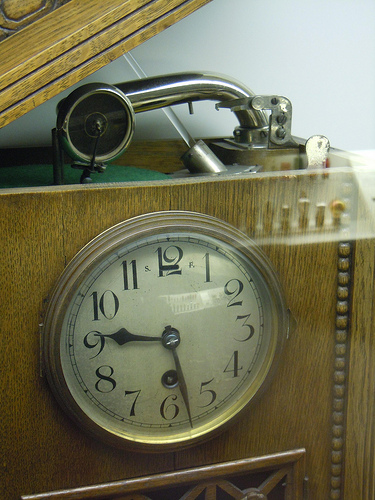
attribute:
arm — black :
[90, 328, 164, 350]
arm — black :
[170, 344, 196, 432]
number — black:
[85, 289, 121, 321]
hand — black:
[161, 325, 207, 424]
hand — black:
[95, 321, 182, 352]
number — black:
[114, 382, 155, 439]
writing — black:
[80, 290, 137, 330]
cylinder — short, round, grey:
[178, 132, 238, 181]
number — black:
[87, 360, 120, 395]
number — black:
[199, 377, 216, 408]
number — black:
[236, 314, 260, 344]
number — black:
[131, 232, 192, 289]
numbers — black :
[71, 218, 263, 440]